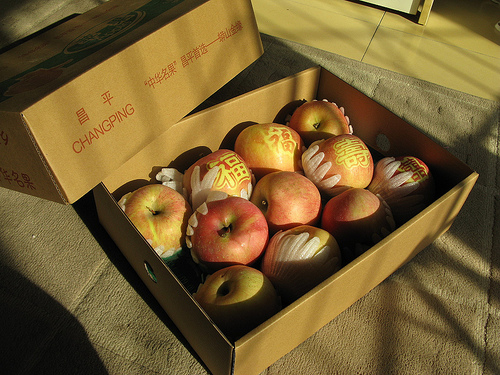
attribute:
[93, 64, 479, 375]
box — large, edged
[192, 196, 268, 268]
apple — red, partial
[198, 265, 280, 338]
apple — yellow, red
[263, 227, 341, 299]
cover — white, soft, protective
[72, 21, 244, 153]
words — red, asian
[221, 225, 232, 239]
stem — brown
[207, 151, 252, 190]
lettering — yellow, asian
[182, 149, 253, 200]
apple — red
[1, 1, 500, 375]
rug — brown, gray, partial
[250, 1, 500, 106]
tiles — yellow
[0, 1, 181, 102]
design — green